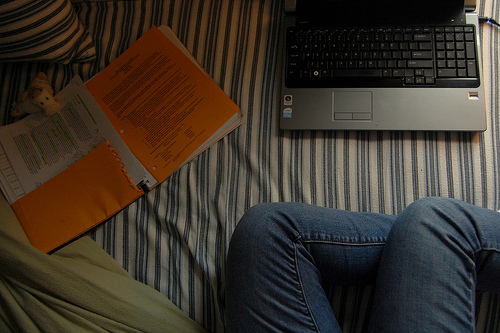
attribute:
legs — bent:
[224, 195, 500, 332]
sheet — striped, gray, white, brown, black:
[1, 1, 499, 330]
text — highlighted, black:
[15, 104, 93, 177]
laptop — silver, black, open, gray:
[280, 1, 485, 135]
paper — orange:
[88, 27, 237, 182]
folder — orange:
[0, 27, 243, 253]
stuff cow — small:
[9, 71, 61, 118]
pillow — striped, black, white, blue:
[1, 1, 97, 67]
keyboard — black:
[286, 24, 479, 89]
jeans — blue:
[222, 199, 495, 332]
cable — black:
[480, 17, 499, 31]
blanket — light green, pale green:
[1, 195, 202, 330]